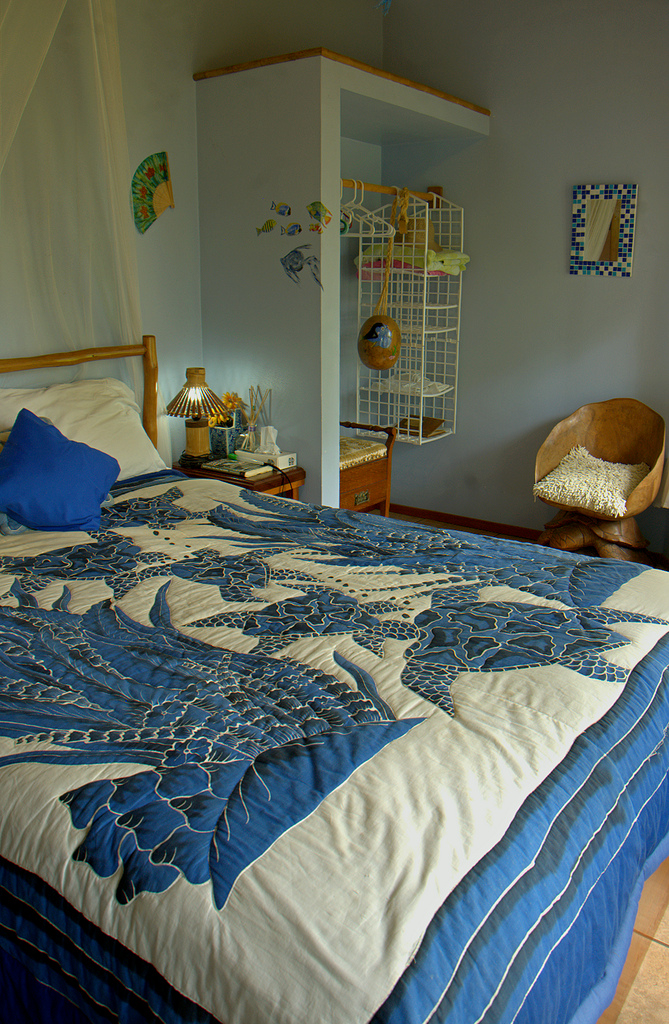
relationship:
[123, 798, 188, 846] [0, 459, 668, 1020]
fabric on blanket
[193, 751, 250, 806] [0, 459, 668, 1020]
fabric on blanket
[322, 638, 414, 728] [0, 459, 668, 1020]
fabric on blanket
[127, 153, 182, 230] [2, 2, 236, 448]
fan hanging wall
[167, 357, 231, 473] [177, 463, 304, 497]
lamp on table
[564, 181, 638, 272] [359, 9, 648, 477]
mirror on wall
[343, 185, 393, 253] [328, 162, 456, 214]
hanger hanging rod